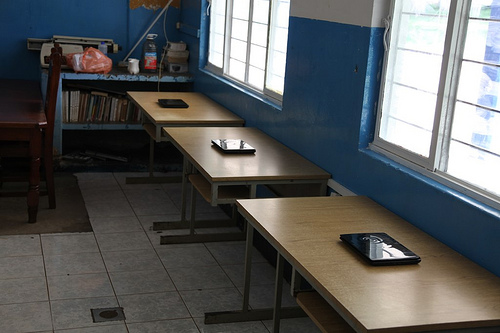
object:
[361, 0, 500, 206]
bars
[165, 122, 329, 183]
taptops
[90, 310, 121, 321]
drain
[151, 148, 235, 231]
tray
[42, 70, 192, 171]
bookshelf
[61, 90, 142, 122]
books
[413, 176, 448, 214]
ground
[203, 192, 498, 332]
wooden desk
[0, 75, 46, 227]
table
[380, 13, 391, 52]
latch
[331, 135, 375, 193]
ground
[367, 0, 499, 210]
window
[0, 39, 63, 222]
chair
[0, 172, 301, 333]
tile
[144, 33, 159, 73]
juice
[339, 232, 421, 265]
laptop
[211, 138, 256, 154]
laptop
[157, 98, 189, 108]
laptop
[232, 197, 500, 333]
desk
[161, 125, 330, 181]
desk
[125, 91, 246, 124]
desk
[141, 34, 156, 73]
bottle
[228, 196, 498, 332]
table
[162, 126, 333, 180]
table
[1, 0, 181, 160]
wall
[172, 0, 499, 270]
wall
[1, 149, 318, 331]
floor